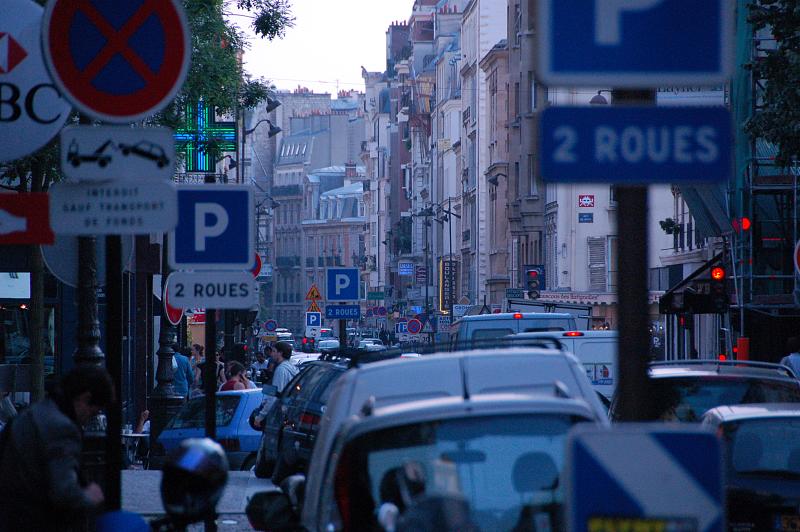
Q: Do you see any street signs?
A: Yes, there is a street sign.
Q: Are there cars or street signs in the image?
A: Yes, there is a street sign.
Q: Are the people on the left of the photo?
A: Yes, the people are on the left of the image.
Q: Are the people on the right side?
A: No, the people are on the left of the image.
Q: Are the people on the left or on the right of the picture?
A: The people are on the left of the image.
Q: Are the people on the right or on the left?
A: The people are on the left of the image.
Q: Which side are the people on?
A: The people are on the left of the image.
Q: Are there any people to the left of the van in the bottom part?
A: Yes, there are people to the left of the van.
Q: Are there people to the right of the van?
A: No, the people are to the left of the van.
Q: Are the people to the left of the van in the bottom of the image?
A: Yes, the people are to the left of the van.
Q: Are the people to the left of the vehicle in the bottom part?
A: Yes, the people are to the left of the van.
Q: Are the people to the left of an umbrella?
A: No, the people are to the left of the van.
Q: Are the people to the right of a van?
A: No, the people are to the left of a van.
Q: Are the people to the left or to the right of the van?
A: The people are to the left of the van.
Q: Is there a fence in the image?
A: No, there are no fences.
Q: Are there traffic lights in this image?
A: Yes, there is a traffic light.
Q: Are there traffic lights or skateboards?
A: Yes, there is a traffic light.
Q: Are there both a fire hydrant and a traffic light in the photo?
A: No, there is a traffic light but no fire hydrants.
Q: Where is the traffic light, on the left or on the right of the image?
A: The traffic light is on the right of the image.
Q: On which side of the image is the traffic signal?
A: The traffic signal is on the right of the image.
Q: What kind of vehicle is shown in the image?
A: The vehicle is a van.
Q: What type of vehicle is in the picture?
A: The vehicle is a van.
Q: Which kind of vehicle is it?
A: The vehicle is a van.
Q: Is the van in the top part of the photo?
A: No, the van is in the bottom of the image.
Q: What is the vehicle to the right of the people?
A: The vehicle is a van.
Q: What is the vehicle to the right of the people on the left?
A: The vehicle is a van.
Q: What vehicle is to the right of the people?
A: The vehicle is a van.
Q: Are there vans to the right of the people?
A: Yes, there is a van to the right of the people.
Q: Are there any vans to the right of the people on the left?
A: Yes, there is a van to the right of the people.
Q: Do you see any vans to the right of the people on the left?
A: Yes, there is a van to the right of the people.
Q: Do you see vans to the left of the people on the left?
A: No, the van is to the right of the people.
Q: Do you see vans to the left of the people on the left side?
A: No, the van is to the right of the people.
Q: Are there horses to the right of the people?
A: No, there is a van to the right of the people.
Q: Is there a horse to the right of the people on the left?
A: No, there is a van to the right of the people.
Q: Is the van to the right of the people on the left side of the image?
A: Yes, the van is to the right of the people.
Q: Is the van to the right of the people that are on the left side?
A: Yes, the van is to the right of the people.